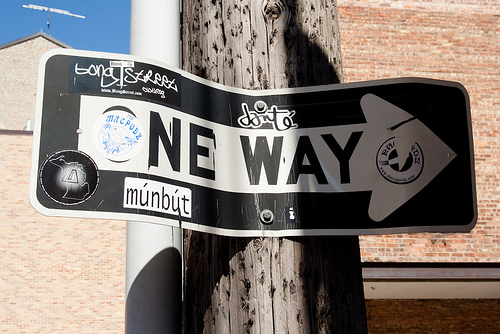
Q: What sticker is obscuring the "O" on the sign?
A: A round blue and white sticker.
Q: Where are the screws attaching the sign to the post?
A: In the center.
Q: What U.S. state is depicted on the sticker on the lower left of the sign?
A: Michigan.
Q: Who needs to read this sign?
A: Drivers of cars.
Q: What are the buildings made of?
A: Brick.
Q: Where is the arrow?
A: On the sign.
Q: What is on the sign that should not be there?
A: Stickers.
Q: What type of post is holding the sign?
A: Wooden.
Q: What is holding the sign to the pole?
A: Nut and washers.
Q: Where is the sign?
A: On the pole.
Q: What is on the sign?
A: An arrow.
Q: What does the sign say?
A: One way.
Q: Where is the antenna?
A: On top of the building.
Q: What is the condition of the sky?
A: Clear.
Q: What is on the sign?
A: Stickers.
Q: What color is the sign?
A: Black.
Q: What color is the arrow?
A: White.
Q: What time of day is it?
A: Daytime.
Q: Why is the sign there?
A: To show direction.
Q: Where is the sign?
A: On the Telephone pole.